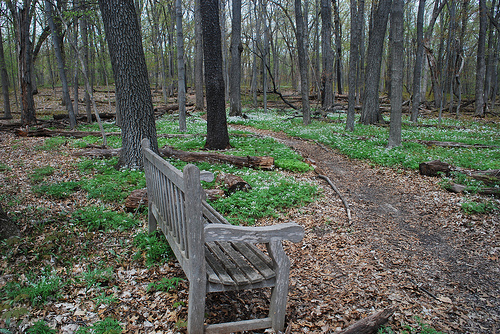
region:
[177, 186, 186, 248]
wooden slat on bench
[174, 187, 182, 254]
wooden slat on bench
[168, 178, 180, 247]
wooden slat on bench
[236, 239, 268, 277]
wooden slat on bench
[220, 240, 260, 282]
wooden slat on bench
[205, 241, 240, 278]
wooden slat on bench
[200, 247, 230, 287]
wooden slat on bench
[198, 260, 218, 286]
wooden slat on bench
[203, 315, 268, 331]
wooden slat on bench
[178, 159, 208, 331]
wooden slat on bench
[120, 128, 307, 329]
An empty park bench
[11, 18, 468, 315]
this is a nature setting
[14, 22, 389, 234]
this is in a park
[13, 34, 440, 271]
this is a nature park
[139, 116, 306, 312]
this is a bench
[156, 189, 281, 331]
the bench is light brown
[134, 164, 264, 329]
the bench is made of wood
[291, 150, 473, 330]
this is a trail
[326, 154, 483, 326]
the trail is made of dirt and leaves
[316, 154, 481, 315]
the trail is light brown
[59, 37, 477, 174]
this is a forested area